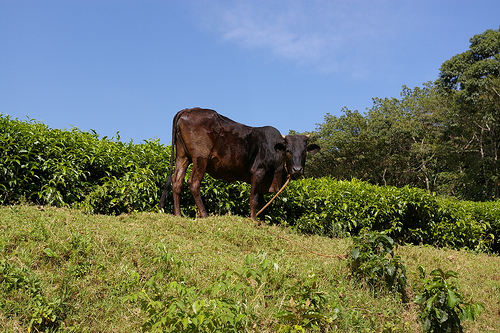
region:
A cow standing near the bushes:
[174, 108, 311, 218]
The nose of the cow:
[292, 161, 302, 173]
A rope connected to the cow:
[256, 171, 299, 213]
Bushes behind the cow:
[5, 115, 499, 253]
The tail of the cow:
[156, 110, 185, 208]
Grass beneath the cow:
[5, 206, 499, 328]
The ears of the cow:
[275, 140, 319, 152]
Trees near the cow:
[283, 28, 498, 173]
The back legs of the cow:
[171, 159, 206, 211]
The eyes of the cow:
[288, 146, 308, 154]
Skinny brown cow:
[157, 91, 314, 231]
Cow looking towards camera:
[171, 99, 311, 221]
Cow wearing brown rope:
[251, 136, 303, 242]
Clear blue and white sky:
[1, 1, 476, 154]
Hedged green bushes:
[1, 118, 499, 261]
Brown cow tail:
[162, 107, 198, 187]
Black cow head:
[274, 128, 321, 177]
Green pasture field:
[1, 194, 498, 331]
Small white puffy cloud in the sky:
[208, 2, 388, 87]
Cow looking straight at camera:
[152, 88, 325, 220]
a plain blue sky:
[14, 13, 491, 148]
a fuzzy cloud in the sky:
[219, 8, 376, 77]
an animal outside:
[176, 106, 313, 221]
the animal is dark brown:
[170, 102, 313, 222]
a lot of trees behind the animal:
[313, 43, 498, 245]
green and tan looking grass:
[9, 202, 489, 332]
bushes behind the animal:
[8, 115, 494, 242]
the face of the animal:
[280, 127, 319, 177]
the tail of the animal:
[163, 108, 183, 225]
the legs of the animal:
[175, 156, 213, 220]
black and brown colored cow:
[162, 90, 326, 235]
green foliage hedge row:
[308, 176, 486, 270]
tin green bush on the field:
[350, 231, 395, 286]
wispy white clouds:
[207, 6, 324, 88]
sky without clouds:
[57, 16, 142, 87]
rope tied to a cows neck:
[248, 161, 293, 224]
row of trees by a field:
[301, 38, 499, 210]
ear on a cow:
[309, 136, 321, 156]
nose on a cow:
[290, 163, 305, 177]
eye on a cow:
[287, 145, 293, 160]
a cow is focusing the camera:
[169, 100, 326, 256]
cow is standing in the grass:
[143, 159, 304, 253]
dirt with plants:
[94, 141, 409, 305]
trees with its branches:
[437, 61, 495, 183]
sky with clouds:
[77, 3, 368, 98]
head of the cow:
[273, 128, 322, 186]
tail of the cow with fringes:
[163, 155, 170, 206]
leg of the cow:
[168, 168, 211, 225]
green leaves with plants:
[332, 188, 467, 228]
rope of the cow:
[261, 175, 288, 237]